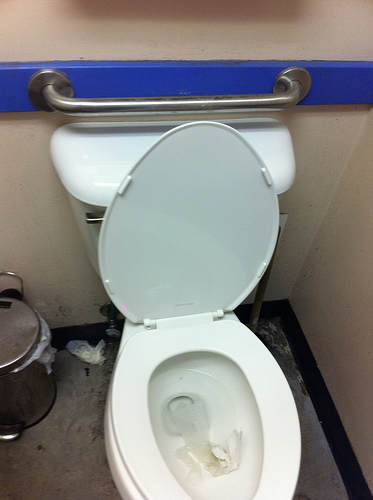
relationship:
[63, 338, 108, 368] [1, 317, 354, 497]
paper sits on floor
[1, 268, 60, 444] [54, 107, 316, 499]
trash can sits near toilet bowl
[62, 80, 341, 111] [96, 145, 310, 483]
bar sits over toilet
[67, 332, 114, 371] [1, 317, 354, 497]
paper on floor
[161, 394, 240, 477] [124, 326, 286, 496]
tissue in toilet bowl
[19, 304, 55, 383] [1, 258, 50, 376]
trash bag in can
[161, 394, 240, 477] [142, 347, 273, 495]
tissue in bowl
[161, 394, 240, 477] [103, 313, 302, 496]
tissue in toilet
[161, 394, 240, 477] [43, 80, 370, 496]
tissue in toilet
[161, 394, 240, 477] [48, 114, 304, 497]
tissue in toilet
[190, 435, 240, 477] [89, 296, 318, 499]
tissue in toilet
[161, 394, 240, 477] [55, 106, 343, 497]
tissue in toilet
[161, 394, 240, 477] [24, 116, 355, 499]
tissue in toilet